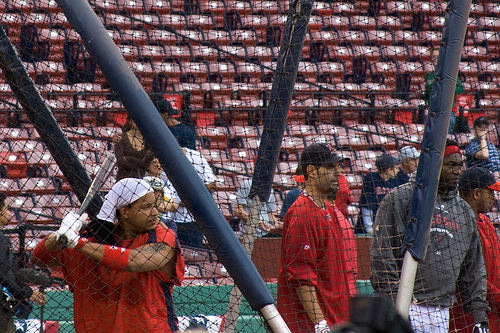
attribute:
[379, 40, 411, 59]
seat — empty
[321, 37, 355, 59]
seat — empty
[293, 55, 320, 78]
seat — empty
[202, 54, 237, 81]
seat — empty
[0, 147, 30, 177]
seat — empty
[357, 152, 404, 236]
spectators — sitting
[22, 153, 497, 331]
team — practicing, professional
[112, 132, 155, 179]
shirt — brown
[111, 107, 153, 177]
woman — standing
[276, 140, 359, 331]
man — standing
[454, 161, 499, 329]
players — practicing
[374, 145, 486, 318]
players — practicing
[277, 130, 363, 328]
players — practicing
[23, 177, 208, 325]
players — practicing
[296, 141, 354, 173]
cap — black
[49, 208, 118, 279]
gloves — white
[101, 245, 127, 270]
band — red, white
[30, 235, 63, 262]
band — white, red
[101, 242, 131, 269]
armband — red, white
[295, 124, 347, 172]
hat — black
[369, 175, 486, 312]
sweatshirt — gray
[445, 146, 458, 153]
headband — red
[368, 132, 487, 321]
man — large, colored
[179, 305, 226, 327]
flag — US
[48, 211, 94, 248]
gloves — white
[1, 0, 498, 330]
netting — black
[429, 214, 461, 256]
logo — Boston Red Sox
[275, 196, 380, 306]
shirt — red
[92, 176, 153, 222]
cloth — white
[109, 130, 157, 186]
shirt — brown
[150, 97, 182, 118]
hat — backwards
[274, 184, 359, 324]
shirt — red, sleeves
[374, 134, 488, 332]
man — standing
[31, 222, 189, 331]
shirt — red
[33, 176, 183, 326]
man — colored, standing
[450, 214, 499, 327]
shirt — red